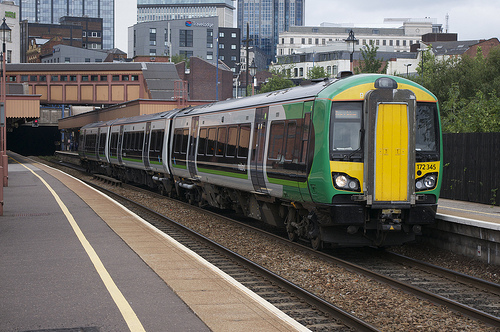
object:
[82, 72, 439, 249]
train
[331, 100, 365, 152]
window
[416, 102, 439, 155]
window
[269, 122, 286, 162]
window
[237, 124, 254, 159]
window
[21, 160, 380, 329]
track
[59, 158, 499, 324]
track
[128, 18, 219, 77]
building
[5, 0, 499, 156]
background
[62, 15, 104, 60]
building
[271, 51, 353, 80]
building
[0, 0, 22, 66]
building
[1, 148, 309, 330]
platform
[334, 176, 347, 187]
light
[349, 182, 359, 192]
light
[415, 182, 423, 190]
light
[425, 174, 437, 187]
light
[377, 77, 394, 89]
light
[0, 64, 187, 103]
bridge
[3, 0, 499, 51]
sky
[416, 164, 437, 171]
number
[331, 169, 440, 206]
face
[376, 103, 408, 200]
door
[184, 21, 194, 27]
logo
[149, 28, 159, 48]
window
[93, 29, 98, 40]
window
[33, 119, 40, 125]
stoplight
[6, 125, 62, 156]
tunnel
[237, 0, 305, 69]
skyscraper